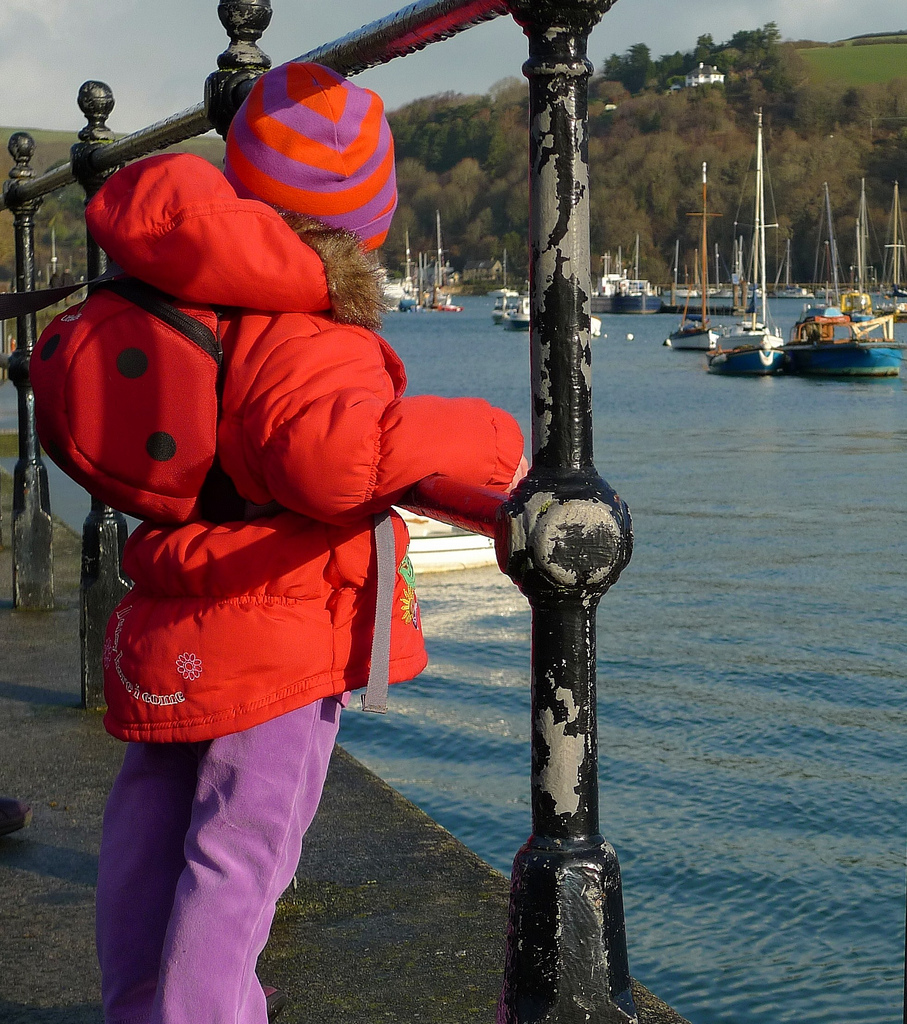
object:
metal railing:
[494, 0, 639, 1019]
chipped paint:
[532, 685, 585, 817]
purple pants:
[95, 698, 342, 1021]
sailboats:
[668, 106, 784, 374]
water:
[381, 296, 906, 1019]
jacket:
[84, 151, 525, 743]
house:
[685, 61, 725, 85]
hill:
[795, 28, 907, 82]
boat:
[705, 321, 785, 375]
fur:
[272, 203, 398, 334]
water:
[634, 386, 906, 1019]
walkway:
[0, 465, 95, 1020]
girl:
[29, 61, 529, 1020]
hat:
[225, 61, 399, 253]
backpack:
[29, 279, 219, 525]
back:
[195, 325, 288, 527]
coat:
[241, 386, 524, 528]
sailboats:
[776, 309, 907, 377]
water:
[634, 408, 835, 570]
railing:
[495, 832, 637, 1024]